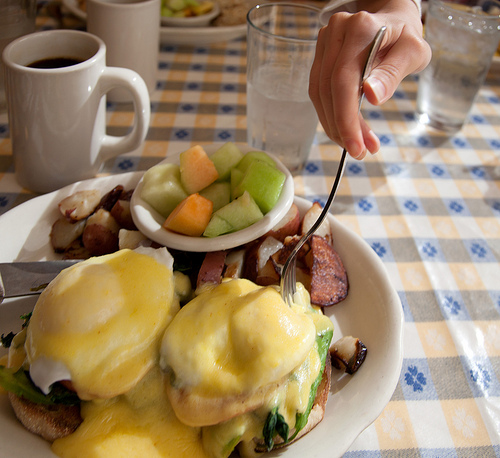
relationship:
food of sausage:
[301, 232, 351, 310] [304, 230, 352, 301]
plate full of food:
[2, 165, 402, 454] [23, 247, 339, 456]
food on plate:
[19, 240, 339, 438] [2, 165, 402, 454]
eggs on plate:
[155, 269, 318, 428] [2, 165, 402, 454]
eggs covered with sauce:
[23, 240, 173, 406] [73, 343, 105, 364]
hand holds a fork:
[308, 3, 435, 164] [274, 25, 386, 286]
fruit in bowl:
[170, 143, 268, 237] [139, 137, 295, 248]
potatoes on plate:
[300, 200, 354, 301] [2, 165, 402, 454]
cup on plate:
[6, 29, 150, 195] [2, 165, 402, 454]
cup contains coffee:
[6, 29, 150, 195] [37, 60, 67, 68]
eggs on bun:
[23, 246, 317, 390] [15, 325, 95, 443]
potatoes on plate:
[55, 172, 352, 311] [2, 165, 402, 454]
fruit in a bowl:
[142, 142, 282, 235] [125, 136, 298, 256]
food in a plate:
[4, 182, 366, 452] [2, 165, 402, 454]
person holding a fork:
[309, 2, 486, 161] [280, 25, 388, 303]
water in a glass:
[246, 61, 313, 170] [243, 2, 326, 172]